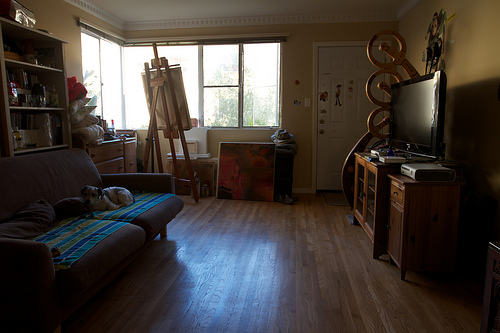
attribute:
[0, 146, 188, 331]
couch — brown, tan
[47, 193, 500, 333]
floor — wooden, wood floor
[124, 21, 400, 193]
wall — light, yellow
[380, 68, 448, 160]
tv — flat screen, flat, black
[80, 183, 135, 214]
dog — black, white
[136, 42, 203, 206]
art easel — wooden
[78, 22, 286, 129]
windows — uncovered, bare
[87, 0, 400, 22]
ceiling — white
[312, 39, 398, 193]
door — shut, white, closed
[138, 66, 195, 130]
canvas — blank, large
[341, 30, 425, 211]
sculpture — wooden, large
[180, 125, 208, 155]
canvas — blank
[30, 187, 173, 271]
cloth — multi-colored